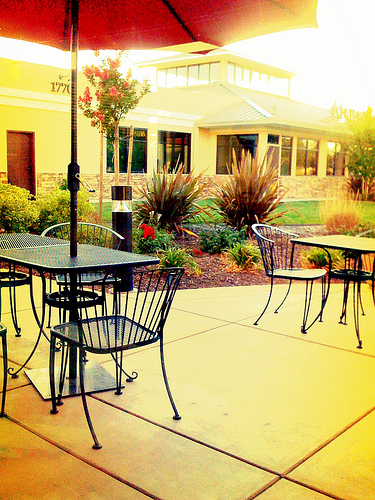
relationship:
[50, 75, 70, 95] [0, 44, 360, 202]
1770 on building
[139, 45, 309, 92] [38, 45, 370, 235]
balcony on building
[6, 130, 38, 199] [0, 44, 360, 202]
door on building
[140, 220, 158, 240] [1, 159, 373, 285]
flowers in garden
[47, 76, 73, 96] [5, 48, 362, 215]
1770 on building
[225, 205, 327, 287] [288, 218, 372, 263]
chair on table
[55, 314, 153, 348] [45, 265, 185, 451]
mesh wire on chair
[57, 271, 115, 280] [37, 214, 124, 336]
mesh wire on chair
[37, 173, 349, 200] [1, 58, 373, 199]
stone wall on building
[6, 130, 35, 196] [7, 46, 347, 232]
door on building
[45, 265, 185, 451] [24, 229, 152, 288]
chair around table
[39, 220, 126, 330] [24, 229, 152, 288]
chair around table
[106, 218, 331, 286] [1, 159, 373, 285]
mulch in garden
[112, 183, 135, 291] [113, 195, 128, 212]
pole with light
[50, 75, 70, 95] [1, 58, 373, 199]
1770 on building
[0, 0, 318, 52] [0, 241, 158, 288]
red umbrella through table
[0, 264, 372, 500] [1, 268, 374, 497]
floor in ground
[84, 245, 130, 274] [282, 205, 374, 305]
part of table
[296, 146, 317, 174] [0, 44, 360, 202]
glass on building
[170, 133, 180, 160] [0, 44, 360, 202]
glass on building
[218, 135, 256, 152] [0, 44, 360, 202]
glass on building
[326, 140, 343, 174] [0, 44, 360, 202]
glass on building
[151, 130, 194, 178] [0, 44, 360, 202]
windows on building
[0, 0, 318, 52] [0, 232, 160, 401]
red umbrella on table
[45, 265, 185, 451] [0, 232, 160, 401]
chair in front of table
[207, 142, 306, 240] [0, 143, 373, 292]
bush in garden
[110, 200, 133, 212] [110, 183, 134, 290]
light on pole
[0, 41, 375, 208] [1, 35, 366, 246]
building on top of building